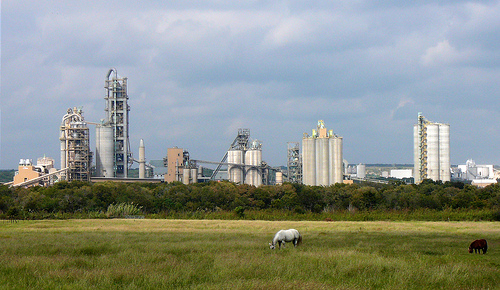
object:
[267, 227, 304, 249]
horse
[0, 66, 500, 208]
factory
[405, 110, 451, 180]
building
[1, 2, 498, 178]
cloudy sky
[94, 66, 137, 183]
building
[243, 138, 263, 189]
silo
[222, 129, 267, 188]
building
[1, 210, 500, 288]
grass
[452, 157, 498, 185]
building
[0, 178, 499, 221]
trees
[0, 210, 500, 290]
field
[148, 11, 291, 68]
clouds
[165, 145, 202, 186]
building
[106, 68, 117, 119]
pipe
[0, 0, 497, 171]
sky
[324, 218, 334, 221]
horse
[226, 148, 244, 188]
silo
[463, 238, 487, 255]
brown horse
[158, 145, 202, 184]
buildings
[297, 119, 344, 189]
buildings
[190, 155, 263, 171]
conveyor belt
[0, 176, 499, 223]
area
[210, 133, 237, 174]
conveyer belt